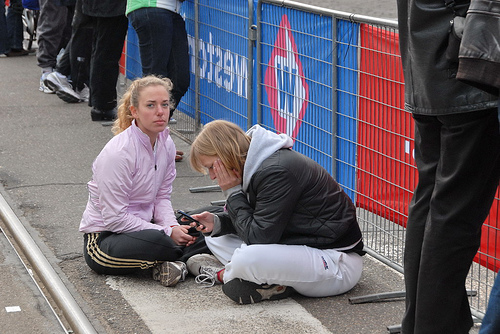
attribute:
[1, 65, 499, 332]
sidewalk — dirty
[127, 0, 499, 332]
fence — metal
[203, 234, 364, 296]
pants — white, black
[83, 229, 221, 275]
pants — black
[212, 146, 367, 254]
jacket — black, pink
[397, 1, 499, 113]
jacket — leather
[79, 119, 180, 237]
jacket — pink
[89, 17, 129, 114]
pants — black